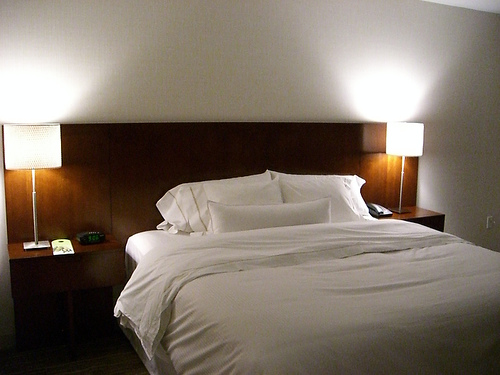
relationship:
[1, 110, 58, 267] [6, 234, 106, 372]
lamp on night stand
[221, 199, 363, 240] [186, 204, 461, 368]
pillow on bed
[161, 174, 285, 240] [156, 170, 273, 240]
pillowcase on pillow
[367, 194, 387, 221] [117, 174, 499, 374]
phone by bed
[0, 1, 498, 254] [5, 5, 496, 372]
wall in room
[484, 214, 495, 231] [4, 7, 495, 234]
outlet on wall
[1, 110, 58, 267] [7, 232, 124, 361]
lamp on desk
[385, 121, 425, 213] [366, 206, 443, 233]
lamp on desk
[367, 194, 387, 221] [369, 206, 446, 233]
phone on desk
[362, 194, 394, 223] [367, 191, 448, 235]
gray phone sitting on night stand